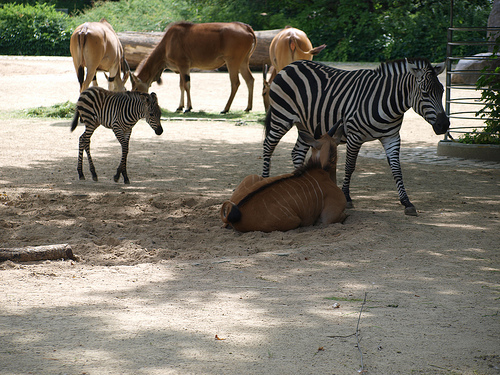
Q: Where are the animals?
A: In the zoo.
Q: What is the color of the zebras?
A: Black and white.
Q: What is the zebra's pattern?
A: Stripes.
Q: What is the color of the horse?
A: Brown.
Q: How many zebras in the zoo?
A: Two.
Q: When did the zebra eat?
A: Earlier.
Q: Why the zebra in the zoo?
A: To take care of.